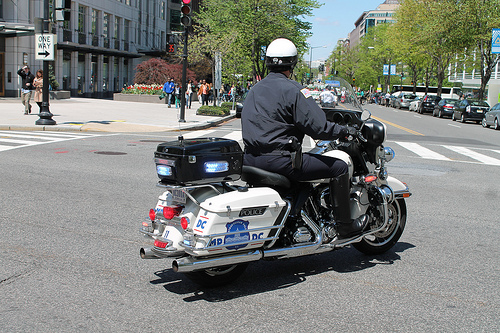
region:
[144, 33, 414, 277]
Man riding a motorcycle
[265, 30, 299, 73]
Black and white helmet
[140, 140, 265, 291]
Back part of a motorcycle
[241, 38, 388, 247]
Man wearing black cothes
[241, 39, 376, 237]
Man wearing black boot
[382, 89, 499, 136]
Cars parked along the street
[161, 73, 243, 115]
People walking on the sidewalk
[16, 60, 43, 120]
Couple walking on the sidewalk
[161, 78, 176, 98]
Man wearing blue sweater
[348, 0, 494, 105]
Trees lined along the street?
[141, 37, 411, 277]
Police officer riding on a motorcycle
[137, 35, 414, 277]
Cop turning left at an intersection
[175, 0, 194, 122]
Traffic light that is red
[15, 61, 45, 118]
Two people walking on a sidewalk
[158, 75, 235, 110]
People walking on a commercial sidewalk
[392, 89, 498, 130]
Cars parked on the side of a road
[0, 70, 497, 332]
Road intersection in a commercial area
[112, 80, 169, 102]
Planted white and red flowers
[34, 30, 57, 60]
One way street traffic sign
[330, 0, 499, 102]
Trees in a line between road and sidewalk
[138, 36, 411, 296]
police man on a motorcycle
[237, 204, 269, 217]
black police symbol on saddle bags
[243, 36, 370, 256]
police officer is wearing a helmet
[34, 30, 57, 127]
One way sign on black pole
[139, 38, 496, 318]
police officer is turning down the road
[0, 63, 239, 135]
several people walk on the sidewalk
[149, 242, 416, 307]
shadow of motorcycle on the ground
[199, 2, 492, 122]
trees line both sides of the road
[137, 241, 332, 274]
two long chrome exhaust pipes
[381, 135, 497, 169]
white paint for pedestrian crossing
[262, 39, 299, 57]
police officer has a white motorcycle helmet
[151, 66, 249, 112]
people walking on the sidewalk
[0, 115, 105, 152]
crosswalk for pedistrians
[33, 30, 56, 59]
ONE WAY written on street sign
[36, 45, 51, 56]
black arrow on the sign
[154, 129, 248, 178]
black box on the back of motorcycle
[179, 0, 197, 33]
street light is red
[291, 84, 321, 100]
patch on police officer's sleeve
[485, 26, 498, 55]
banner on the pole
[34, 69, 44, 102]
woman has her arms crossed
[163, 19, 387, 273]
Police officer in intersection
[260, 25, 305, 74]
White helmet on officer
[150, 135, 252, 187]
Black luggage box on motorcycle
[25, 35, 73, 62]
White one way sign with arrow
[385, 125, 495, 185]
White lines painted on road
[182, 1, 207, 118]
Red illuminated traffic signal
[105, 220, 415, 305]
Shadow cast of police bike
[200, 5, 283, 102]
Green trees along street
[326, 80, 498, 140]
Line of cars parked on right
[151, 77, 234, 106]
Crowd walking along sidewalk